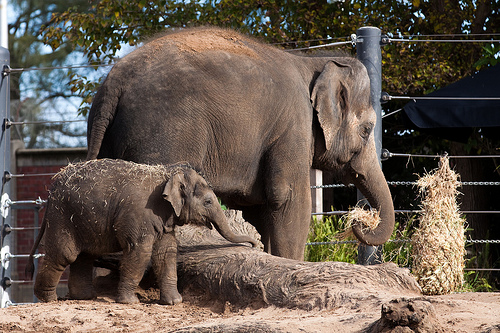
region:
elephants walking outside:
[62, 1, 489, 330]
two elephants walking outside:
[29, 7, 477, 325]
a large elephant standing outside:
[82, 11, 487, 332]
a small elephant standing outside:
[19, 113, 285, 325]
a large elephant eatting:
[152, 21, 498, 278]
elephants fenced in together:
[92, 26, 346, 332]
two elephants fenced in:
[54, 18, 350, 323]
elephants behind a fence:
[51, 27, 368, 316]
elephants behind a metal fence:
[37, 11, 462, 321]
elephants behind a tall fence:
[30, 7, 488, 267]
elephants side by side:
[15, 22, 440, 297]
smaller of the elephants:
[28, 150, 248, 305]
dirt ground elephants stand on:
[7, 293, 497, 327]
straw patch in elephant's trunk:
[341, 201, 379, 229]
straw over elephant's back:
[52, 153, 154, 163]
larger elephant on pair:
[82, 24, 399, 263]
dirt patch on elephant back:
[161, 27, 251, 54]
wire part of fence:
[21, 60, 56, 190]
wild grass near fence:
[316, 203, 488, 285]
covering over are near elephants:
[387, 60, 497, 132]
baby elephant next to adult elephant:
[27, 157, 259, 305]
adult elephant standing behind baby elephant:
[83, 28, 394, 260]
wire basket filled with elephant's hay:
[416, 151, 465, 293]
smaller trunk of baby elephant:
[214, 208, 259, 250]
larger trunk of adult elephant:
[350, 151, 397, 246]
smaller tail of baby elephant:
[23, 198, 47, 278]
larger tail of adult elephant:
[84, 76, 119, 158]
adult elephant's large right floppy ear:
[310, 57, 355, 147]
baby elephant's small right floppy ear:
[160, 169, 188, 218]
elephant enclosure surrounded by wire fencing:
[0, 0, 498, 331]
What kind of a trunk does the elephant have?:
[216, 203, 252, 281]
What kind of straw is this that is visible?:
[428, 154, 474, 281]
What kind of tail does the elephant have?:
[82, 93, 106, 189]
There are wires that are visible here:
[400, 32, 422, 93]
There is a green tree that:
[71, 10, 91, 51]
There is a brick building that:
[26, 174, 39, 251]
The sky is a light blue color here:
[10, 3, 18, 25]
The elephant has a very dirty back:
[173, 15, 263, 96]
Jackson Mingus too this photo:
[106, 38, 388, 208]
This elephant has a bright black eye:
[204, 193, 214, 203]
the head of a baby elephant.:
[306, 45, 409, 267]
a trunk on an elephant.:
[349, 154, 401, 264]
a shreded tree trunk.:
[401, 153, 480, 294]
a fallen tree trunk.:
[160, 203, 432, 311]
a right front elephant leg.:
[254, 102, 331, 262]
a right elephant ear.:
[294, 62, 362, 174]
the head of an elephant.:
[156, 148, 270, 263]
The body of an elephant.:
[61, 168, 159, 228]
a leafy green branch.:
[6, 0, 127, 58]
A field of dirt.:
[0, 276, 497, 330]